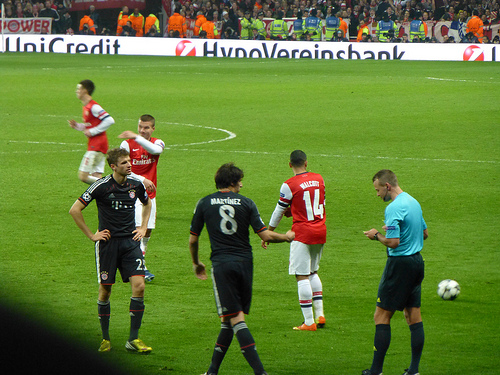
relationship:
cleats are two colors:
[99, 336, 156, 356] [127, 342, 151, 354]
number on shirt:
[300, 188, 327, 222] [274, 171, 336, 245]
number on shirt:
[212, 199, 240, 240] [183, 190, 269, 256]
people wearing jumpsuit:
[77, 11, 98, 36] [80, 17, 96, 29]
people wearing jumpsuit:
[117, 10, 163, 34] [117, 17, 159, 35]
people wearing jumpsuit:
[166, 13, 217, 34] [169, 14, 216, 34]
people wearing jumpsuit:
[465, 10, 483, 40] [465, 18, 483, 42]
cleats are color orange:
[291, 315, 333, 333] [303, 326, 316, 332]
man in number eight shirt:
[187, 155, 302, 374] [183, 190, 269, 256]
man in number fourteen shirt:
[264, 150, 331, 333] [274, 171, 336, 245]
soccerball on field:
[436, 276, 465, 302] [3, 52, 498, 374]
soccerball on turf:
[436, 276, 465, 302] [3, 52, 498, 374]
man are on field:
[188, 163, 296, 374] [3, 52, 498, 374]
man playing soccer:
[188, 163, 296, 374] [436, 276, 465, 302]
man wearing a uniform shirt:
[187, 155, 302, 374] [183, 190, 269, 256]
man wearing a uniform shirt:
[264, 150, 331, 333] [274, 171, 336, 245]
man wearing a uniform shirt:
[61, 150, 155, 358] [74, 174, 158, 242]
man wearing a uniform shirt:
[70, 77, 117, 185] [78, 102, 116, 156]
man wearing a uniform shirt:
[118, 106, 171, 286] [117, 133, 167, 200]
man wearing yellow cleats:
[61, 150, 155, 358] [99, 336, 156, 356]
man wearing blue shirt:
[361, 170, 433, 374] [379, 193, 431, 255]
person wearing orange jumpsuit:
[77, 11, 98, 36] [80, 17, 96, 29]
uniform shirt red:
[274, 171, 336, 245] [296, 199, 302, 227]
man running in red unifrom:
[70, 77, 117, 185] [75, 99, 113, 174]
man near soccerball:
[361, 170, 433, 374] [436, 276, 465, 302]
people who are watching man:
[0, 0, 499, 45] [188, 163, 296, 374]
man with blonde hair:
[61, 150, 155, 358] [107, 146, 134, 169]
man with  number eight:
[187, 155, 302, 374] [212, 199, 240, 240]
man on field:
[188, 163, 296, 374] [3, 52, 498, 374]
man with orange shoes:
[264, 150, 331, 333] [291, 315, 333, 333]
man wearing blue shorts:
[187, 155, 302, 374] [206, 253, 256, 318]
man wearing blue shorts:
[61, 150, 155, 358] [91, 236, 148, 280]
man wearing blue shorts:
[361, 170, 433, 374] [372, 249, 426, 314]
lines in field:
[4, 108, 500, 174] [3, 52, 498, 374]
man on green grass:
[188, 163, 296, 374] [3, 52, 498, 374]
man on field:
[118, 115, 171, 287] [3, 52, 498, 374]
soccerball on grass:
[436, 276, 465, 302] [3, 52, 498, 374]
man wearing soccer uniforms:
[118, 115, 171, 287] [266, 174, 338, 320]